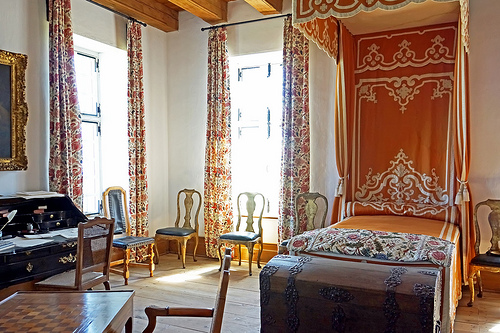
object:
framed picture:
[0, 39, 31, 182]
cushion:
[216, 225, 264, 242]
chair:
[153, 186, 203, 270]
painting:
[0, 67, 14, 161]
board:
[2, 285, 144, 331]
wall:
[139, 28, 225, 225]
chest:
[249, 250, 438, 330]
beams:
[98, 2, 232, 32]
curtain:
[46, 1, 88, 217]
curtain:
[122, 17, 155, 262]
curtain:
[200, 26, 234, 263]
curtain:
[273, 14, 314, 258]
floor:
[92, 237, 499, 331]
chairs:
[87, 171, 287, 273]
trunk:
[255, 247, 442, 332]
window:
[60, 20, 344, 237]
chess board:
[18, 259, 173, 331]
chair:
[213, 188, 267, 278]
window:
[228, 54, 284, 213]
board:
[1, 298, 108, 330]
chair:
[102, 188, 152, 283]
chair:
[465, 194, 499, 306]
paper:
[1, 224, 86, 251]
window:
[47, 27, 142, 182]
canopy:
[290, 0, 479, 103]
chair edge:
[217, 232, 254, 242]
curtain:
[347, 27, 462, 224]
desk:
[6, 193, 106, 289]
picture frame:
[2, 95, 37, 173]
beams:
[129, 6, 282, 31]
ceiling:
[178, 13, 200, 41]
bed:
[279, 188, 475, 332]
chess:
[7, 288, 114, 330]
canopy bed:
[290, 0, 473, 329]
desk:
[0, 186, 106, 288]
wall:
[0, 3, 53, 204]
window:
[231, 55, 276, 146]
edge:
[325, 246, 380, 256]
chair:
[201, 185, 301, 283]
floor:
[136, 248, 213, 330]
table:
[0, 284, 144, 333]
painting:
[4, 33, 35, 185]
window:
[65, 35, 123, 192]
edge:
[430, 217, 460, 300]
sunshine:
[157, 243, 233, 294]